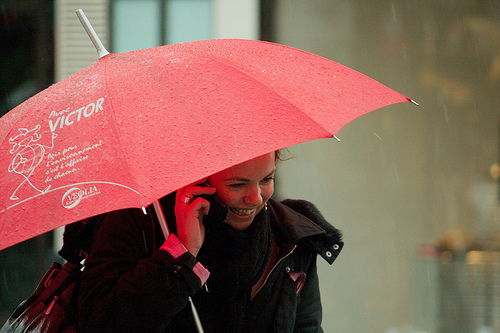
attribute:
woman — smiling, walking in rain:
[84, 148, 328, 331]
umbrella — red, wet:
[3, 7, 418, 330]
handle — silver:
[150, 192, 212, 332]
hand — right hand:
[171, 176, 220, 258]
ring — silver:
[180, 195, 191, 206]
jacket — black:
[81, 194, 334, 332]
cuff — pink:
[162, 234, 214, 287]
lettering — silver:
[43, 97, 124, 185]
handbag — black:
[1, 214, 127, 330]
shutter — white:
[51, 4, 110, 79]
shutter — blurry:
[210, 3, 267, 44]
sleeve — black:
[78, 212, 199, 330]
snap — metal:
[325, 249, 331, 258]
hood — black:
[272, 193, 351, 272]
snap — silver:
[331, 242, 346, 253]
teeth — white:
[230, 204, 256, 214]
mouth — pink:
[228, 203, 263, 218]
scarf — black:
[207, 210, 275, 332]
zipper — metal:
[246, 238, 304, 295]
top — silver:
[75, 7, 110, 62]